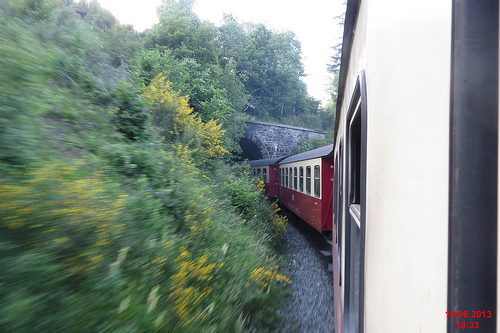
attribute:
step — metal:
[318, 236, 337, 257]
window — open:
[346, 79, 363, 332]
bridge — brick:
[244, 120, 336, 159]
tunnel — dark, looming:
[229, 137, 268, 163]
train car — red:
[278, 144, 334, 234]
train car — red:
[253, 155, 286, 194]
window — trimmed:
[311, 164, 324, 195]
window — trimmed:
[263, 167, 269, 182]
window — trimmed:
[305, 167, 311, 193]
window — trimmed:
[298, 164, 306, 189]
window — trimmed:
[292, 167, 298, 189]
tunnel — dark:
[232, 136, 259, 161]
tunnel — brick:
[214, 114, 279, 161]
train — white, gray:
[231, 2, 483, 329]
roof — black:
[249, 141, 337, 170]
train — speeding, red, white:
[241, 1, 498, 331]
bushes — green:
[12, 2, 279, 329]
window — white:
[309, 162, 323, 199]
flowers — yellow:
[142, 76, 239, 178]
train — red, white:
[251, 133, 333, 224]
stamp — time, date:
[442, 305, 490, 332]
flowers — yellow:
[139, 70, 229, 194]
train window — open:
[342, 69, 366, 234]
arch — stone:
[227, 129, 270, 161]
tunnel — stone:
[230, 133, 266, 162]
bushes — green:
[0, 0, 295, 332]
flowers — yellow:
[0, 71, 291, 330]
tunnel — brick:
[220, 122, 294, 202]